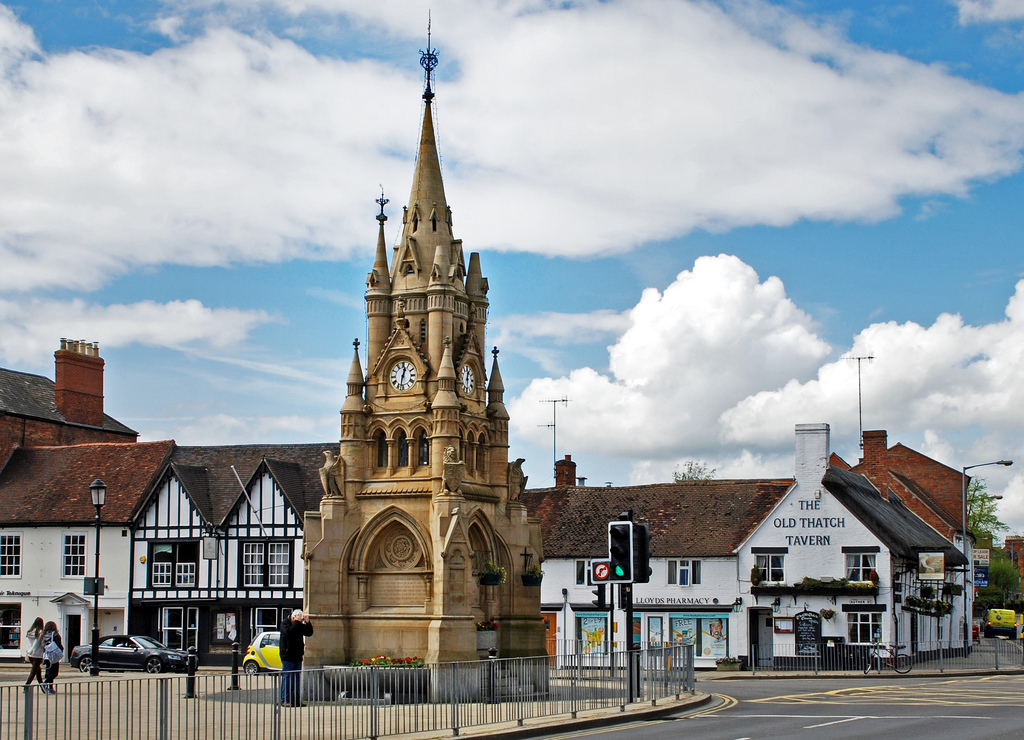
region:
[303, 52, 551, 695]
tan decorative clock tower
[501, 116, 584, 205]
white clouds in blue sky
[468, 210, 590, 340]
white clouds in blue sky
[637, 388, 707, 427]
white clouds in blue sky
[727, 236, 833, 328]
white clouds in blue sky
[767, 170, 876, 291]
white clouds in blue sky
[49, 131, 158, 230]
white clouds in blue sky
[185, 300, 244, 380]
white clouds in blue sky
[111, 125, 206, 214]
white clouds in blue sky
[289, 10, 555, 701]
looks like the top of a building on the ground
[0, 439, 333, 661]
architecture from the Tudor style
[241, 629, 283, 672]
part of a little yellow car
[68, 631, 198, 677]
a dark colored coupe on the street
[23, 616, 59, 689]
a couple of girls walking toward the street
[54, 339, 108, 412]
the chimney of a fireplace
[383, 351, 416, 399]
a clock surrounded by a structure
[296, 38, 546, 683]
clock tower in the middle of square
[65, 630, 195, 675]
black car in street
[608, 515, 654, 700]
black traffic light in sidewalk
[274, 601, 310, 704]
man wearing black jacket in front of clock tower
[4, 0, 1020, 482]
light blue sky with white clouds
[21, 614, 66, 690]
women walking together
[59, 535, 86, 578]
window facing clock tower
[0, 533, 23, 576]
window facing clock tower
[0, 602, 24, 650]
window facing clock tower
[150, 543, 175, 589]
window facing clock tower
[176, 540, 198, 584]
window facing clock tower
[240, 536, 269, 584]
window facing clock tower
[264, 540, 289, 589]
window facing clock tower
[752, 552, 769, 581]
window facing clock tower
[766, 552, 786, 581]
window facing clock tower